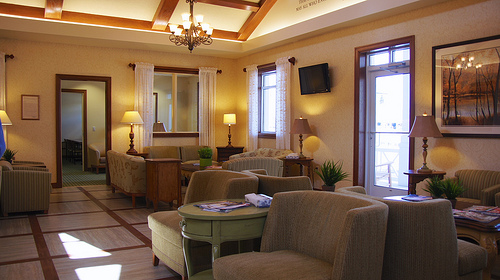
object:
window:
[153, 71, 199, 132]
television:
[294, 101, 328, 134]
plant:
[423, 173, 445, 208]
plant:
[441, 174, 461, 209]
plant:
[312, 154, 348, 194]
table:
[455, 199, 500, 280]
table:
[181, 159, 223, 174]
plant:
[196, 142, 213, 169]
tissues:
[244, 193, 273, 209]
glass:
[369, 74, 409, 184]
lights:
[160, 1, 217, 55]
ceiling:
[0, 1, 367, 44]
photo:
[2, 3, 499, 278]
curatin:
[133, 61, 154, 153]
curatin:
[196, 65, 216, 159]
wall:
[3, 30, 235, 190]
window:
[358, 43, 410, 191]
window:
[259, 69, 281, 136]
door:
[56, 77, 110, 188]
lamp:
[408, 111, 441, 171]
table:
[403, 169, 445, 194]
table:
[179, 191, 276, 278]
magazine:
[193, 199, 251, 214]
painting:
[431, 34, 498, 139]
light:
[457, 53, 482, 70]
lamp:
[290, 116, 312, 158]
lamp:
[1, 108, 13, 160]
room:
[1, 1, 491, 278]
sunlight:
[56, 228, 121, 278]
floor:
[0, 182, 185, 278]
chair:
[213, 190, 391, 279]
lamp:
[117, 109, 145, 156]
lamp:
[220, 110, 240, 149]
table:
[124, 152, 149, 159]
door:
[357, 43, 408, 199]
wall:
[333, 102, 349, 148]